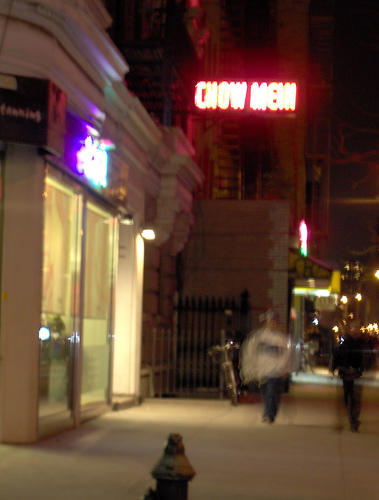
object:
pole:
[160, 330, 164, 392]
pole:
[167, 325, 171, 397]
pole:
[173, 326, 179, 391]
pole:
[179, 328, 185, 397]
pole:
[186, 328, 191, 394]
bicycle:
[207, 340, 240, 406]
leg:
[262, 380, 274, 424]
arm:
[244, 330, 267, 353]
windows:
[84, 204, 115, 401]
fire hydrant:
[143, 432, 196, 499]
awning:
[288, 247, 334, 287]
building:
[105, 0, 310, 398]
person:
[329, 329, 370, 433]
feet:
[350, 419, 361, 432]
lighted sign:
[75, 134, 109, 189]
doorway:
[36, 160, 121, 438]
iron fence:
[150, 286, 251, 400]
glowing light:
[134, 233, 145, 272]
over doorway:
[112, 212, 145, 413]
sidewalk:
[0, 388, 379, 498]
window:
[43, 180, 81, 407]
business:
[0, 0, 208, 448]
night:
[0, 4, 376, 500]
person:
[239, 306, 294, 427]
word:
[194, 80, 247, 108]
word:
[248, 81, 296, 110]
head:
[342, 331, 350, 342]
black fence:
[175, 288, 250, 393]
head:
[259, 307, 275, 324]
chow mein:
[194, 81, 298, 112]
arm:
[331, 343, 342, 368]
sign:
[194, 80, 296, 112]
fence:
[150, 330, 228, 399]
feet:
[266, 413, 275, 424]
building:
[0, 0, 208, 444]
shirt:
[250, 329, 284, 379]